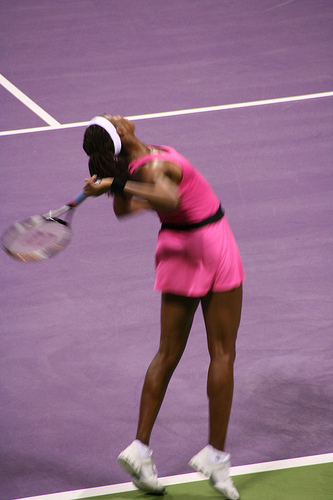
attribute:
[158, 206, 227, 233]
belt — Black 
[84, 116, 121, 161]
band — white 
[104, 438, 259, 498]
shoe — white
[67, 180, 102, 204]
grip — blue 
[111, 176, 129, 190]
band — black 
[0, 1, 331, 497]
surface — purple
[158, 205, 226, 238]
belt — black 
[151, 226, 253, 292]
skirt — pink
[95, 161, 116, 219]
headband — white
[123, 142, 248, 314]
skirt — pink 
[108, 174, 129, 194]
wristband — black